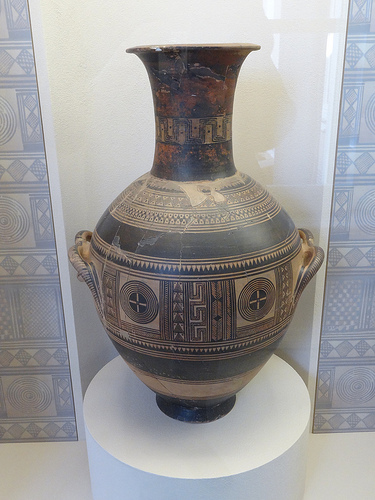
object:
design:
[155, 264, 246, 349]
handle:
[275, 227, 326, 307]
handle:
[67, 229, 95, 299]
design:
[103, 249, 165, 344]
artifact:
[67, 41, 327, 427]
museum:
[16, 27, 103, 199]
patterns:
[95, 254, 284, 346]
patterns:
[111, 265, 160, 337]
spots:
[180, 175, 225, 208]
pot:
[66, 37, 327, 426]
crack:
[98, 214, 121, 289]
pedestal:
[77, 353, 314, 498]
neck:
[144, 68, 240, 177]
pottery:
[62, 37, 329, 427]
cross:
[249, 290, 266, 310]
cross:
[129, 293, 146, 312]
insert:
[66, 4, 351, 401]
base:
[152, 391, 239, 425]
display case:
[25, 0, 354, 499]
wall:
[0, 0, 362, 443]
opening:
[122, 39, 263, 58]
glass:
[26, 1, 352, 481]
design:
[234, 276, 280, 325]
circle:
[237, 275, 276, 323]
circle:
[119, 278, 159, 324]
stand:
[77, 368, 315, 500]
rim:
[111, 20, 280, 64]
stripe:
[86, 214, 310, 298]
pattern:
[5, 78, 86, 434]